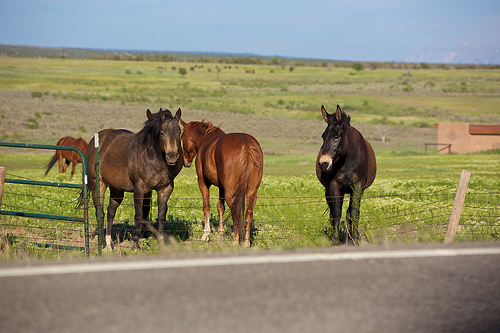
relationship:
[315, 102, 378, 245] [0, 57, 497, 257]
horse in field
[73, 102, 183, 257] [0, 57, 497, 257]
horse in field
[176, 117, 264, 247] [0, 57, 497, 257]
horse in field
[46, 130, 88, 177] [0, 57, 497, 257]
horse in field